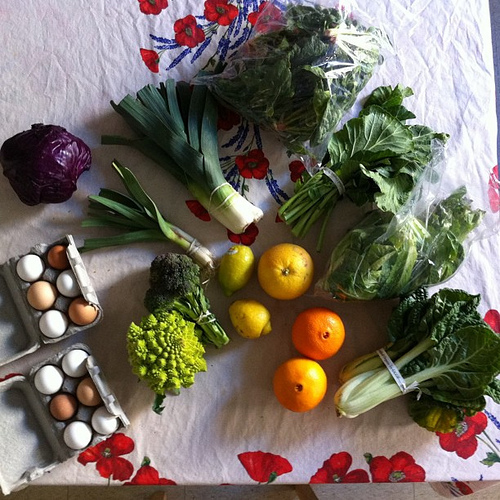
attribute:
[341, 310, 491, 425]
vegetable — green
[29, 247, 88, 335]
eggs — multi-color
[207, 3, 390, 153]
chard — swiss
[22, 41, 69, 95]
cloth — white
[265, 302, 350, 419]
navel oranges — lying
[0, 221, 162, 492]
egg — brown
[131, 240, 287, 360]
broccoli — large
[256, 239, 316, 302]
grapefruit — lying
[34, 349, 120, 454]
eggs — brown, white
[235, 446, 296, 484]
flower — red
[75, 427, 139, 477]
flower — red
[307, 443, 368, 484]
flower — red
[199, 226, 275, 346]
lemons — lying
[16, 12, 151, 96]
tablecloth — patterned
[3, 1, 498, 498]
tablecloth — old , wrinkled, cotton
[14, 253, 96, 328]
eggs — brown, white